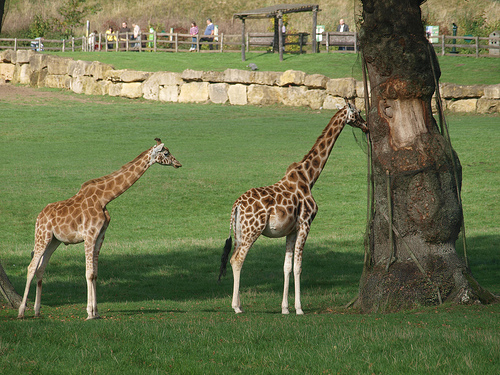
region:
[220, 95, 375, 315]
giraffe near a tree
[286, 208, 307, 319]
leg of a griaffe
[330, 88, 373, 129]
head of a griaffe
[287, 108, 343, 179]
neck of a giraffe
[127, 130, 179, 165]
head of a giraffe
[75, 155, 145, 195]
neck of a giraffe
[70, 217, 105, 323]
leg of a giraffe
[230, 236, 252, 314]
leg of a giraffe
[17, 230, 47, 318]
leg of a giraffe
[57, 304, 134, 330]
Dried leaves on the grass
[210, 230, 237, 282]
The black hair on the tail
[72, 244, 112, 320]
A long and slender leg of a giraffe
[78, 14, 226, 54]
People watching in the background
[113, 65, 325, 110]
Big stones used as a wall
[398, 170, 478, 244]
A bulge on the side of a log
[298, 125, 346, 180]
A long neck of a giraffe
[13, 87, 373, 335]
giraffes hanging out in their habitat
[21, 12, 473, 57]
visitors observe the wildlife from afar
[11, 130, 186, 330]
smaller giraffe might be an immature youngster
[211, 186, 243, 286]
giraffe has a very long thin tail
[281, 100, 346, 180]
giraffe has a very short stiff mane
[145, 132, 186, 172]
giraffe has short tufted horns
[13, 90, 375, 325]
giraffe coloring differs among the animals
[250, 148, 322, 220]
giraffe has two-tone spots in places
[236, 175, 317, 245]
giraffe's spots fit together like an interlocking mosaic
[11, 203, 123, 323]
giraffe's front legs are longer than its back legs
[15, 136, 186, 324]
small young giraffe standing near other giraffe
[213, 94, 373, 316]
small young giraffe next to tree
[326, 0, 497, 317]
dark brown and gray thick tree trunk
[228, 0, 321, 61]
brown and gray wooden shelter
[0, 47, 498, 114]
long gray yellow white and brown stone wall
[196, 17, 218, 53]
man in blue shirt next to fence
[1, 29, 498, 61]
light gray and brown wooden fence around giraffe enclosure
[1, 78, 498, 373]
large green grassy field with giraffes on it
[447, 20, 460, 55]
green telescope next to giraffe enclosure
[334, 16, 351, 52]
man wearing gray jacket next to fence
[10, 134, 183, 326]
this is a giraffe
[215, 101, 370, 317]
this is a giraffe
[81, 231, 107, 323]
these are his arms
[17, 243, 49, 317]
these are his legs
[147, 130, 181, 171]
this is the giraffe's head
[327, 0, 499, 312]
this is a tree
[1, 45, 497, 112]
this is a brick wall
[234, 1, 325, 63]
this is a gazebo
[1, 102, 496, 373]
this is the green grass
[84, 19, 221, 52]
these are people watching the animals